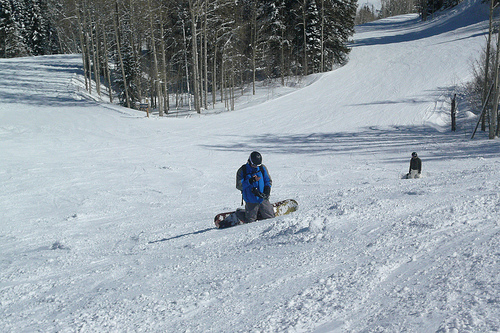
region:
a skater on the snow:
[210, 141, 305, 234]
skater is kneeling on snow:
[230, 146, 280, 227]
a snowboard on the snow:
[211, 197, 304, 231]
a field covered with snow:
[0, 19, 498, 331]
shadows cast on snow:
[6, 51, 93, 119]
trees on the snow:
[46, 3, 373, 140]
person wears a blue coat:
[228, 138, 283, 230]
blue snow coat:
[226, 165, 278, 206]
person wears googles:
[232, 146, 277, 188]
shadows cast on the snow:
[356, 9, 484, 73]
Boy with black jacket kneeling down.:
[405, 144, 422, 185]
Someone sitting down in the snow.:
[398, 147, 425, 184]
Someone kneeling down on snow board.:
[218, 140, 303, 222]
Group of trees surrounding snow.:
[93, 51, 275, 118]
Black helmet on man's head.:
[246, 148, 269, 170]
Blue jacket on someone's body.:
[238, 168, 272, 201]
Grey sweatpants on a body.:
[243, 199, 277, 221]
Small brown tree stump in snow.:
[448, 88, 461, 128]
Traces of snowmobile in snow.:
[352, 263, 450, 318]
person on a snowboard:
[207, 143, 305, 234]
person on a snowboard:
[400, 145, 427, 190]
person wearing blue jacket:
[191, 141, 308, 236]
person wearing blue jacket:
[396, 145, 428, 183]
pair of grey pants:
[235, 194, 277, 225]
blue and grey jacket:
[230, 158, 277, 208]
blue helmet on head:
[247, 145, 264, 168]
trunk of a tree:
[137, 10, 172, 112]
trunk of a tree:
[92, 23, 117, 104]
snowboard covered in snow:
[207, 196, 299, 232]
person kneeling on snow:
[405, 145, 431, 185]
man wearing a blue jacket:
[230, 145, 286, 205]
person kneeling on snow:
[196, 147, 307, 232]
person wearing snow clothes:
[212, 143, 282, 228]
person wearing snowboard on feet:
[209, 188, 306, 230]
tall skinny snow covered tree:
[297, 0, 325, 69]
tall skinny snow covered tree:
[240, 3, 276, 105]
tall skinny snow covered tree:
[177, 9, 223, 120]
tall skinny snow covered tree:
[145, 8, 177, 111]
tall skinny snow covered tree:
[104, 12, 141, 113]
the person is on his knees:
[243, 199, 277, 226]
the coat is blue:
[248, 176, 265, 193]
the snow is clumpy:
[277, 214, 321, 238]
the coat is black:
[407, 158, 422, 168]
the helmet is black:
[250, 151, 263, 166]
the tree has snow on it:
[11, 14, 38, 43]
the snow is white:
[96, 157, 132, 188]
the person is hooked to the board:
[213, 204, 251, 234]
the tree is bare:
[143, 2, 162, 31]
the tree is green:
[333, 6, 346, 38]